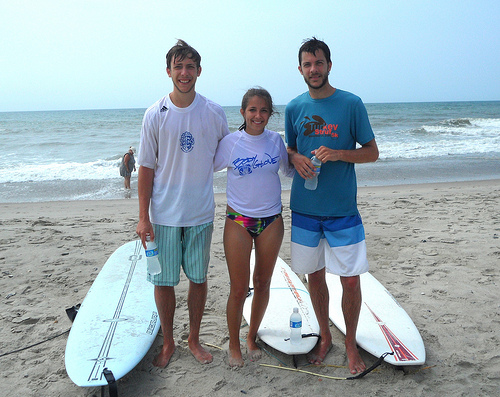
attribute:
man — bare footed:
[268, 47, 376, 293]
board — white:
[62, 237, 162, 389]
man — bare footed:
[133, 39, 222, 369]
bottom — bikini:
[220, 207, 283, 237]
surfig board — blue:
[61, 237, 163, 384]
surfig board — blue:
[238, 240, 323, 353]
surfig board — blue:
[303, 251, 425, 360]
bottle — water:
[291, 145, 335, 202]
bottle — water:
[288, 303, 300, 339]